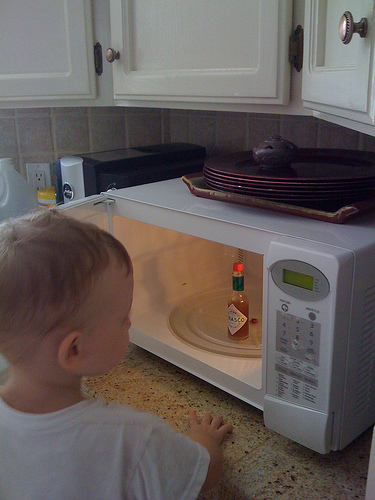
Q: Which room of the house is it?
A: It is a kitchen.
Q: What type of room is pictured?
A: It is a kitchen.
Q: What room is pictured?
A: It is a kitchen.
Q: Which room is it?
A: It is a kitchen.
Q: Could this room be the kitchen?
A: Yes, it is the kitchen.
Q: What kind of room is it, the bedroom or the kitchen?
A: It is the kitchen.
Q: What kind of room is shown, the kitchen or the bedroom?
A: It is the kitchen.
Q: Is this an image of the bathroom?
A: No, the picture is showing the kitchen.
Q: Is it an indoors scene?
A: Yes, it is indoors.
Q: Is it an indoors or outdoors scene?
A: It is indoors.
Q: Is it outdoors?
A: No, it is indoors.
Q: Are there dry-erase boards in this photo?
A: No, there are no dry-erase boards.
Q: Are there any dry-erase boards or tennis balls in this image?
A: No, there are no dry-erase boards or tennis balls.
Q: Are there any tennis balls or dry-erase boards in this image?
A: No, there are no dry-erase boards or tennis balls.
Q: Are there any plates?
A: Yes, there is a plate.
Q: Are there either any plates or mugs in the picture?
A: Yes, there is a plate.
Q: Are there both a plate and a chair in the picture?
A: No, there is a plate but no chairs.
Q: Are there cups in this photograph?
A: No, there are no cups.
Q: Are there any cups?
A: No, there are no cups.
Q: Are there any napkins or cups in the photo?
A: No, there are no cups or napkins.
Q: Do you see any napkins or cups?
A: No, there are no cups or napkins.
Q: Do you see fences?
A: No, there are no fences.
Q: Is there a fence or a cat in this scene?
A: No, there are no fences or cats.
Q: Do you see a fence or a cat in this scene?
A: No, there are no fences or cats.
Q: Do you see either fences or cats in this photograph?
A: No, there are no fences or cats.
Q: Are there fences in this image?
A: No, there are no fences.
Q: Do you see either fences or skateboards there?
A: No, there are no fences or skateboards.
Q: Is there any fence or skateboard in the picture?
A: No, there are no fences or skateboards.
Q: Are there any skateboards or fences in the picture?
A: No, there are no fences or skateboards.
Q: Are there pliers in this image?
A: No, there are no pliers.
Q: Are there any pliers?
A: No, there are no pliers.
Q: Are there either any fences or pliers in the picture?
A: No, there are no pliers or fences.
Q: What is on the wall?
A: The electric outlet is on the wall.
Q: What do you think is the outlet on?
A: The outlet is on the wall.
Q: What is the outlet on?
A: The outlet is on the wall.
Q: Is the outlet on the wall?
A: Yes, the outlet is on the wall.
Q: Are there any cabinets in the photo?
A: Yes, there is a cabinet.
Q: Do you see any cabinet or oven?
A: Yes, there is a cabinet.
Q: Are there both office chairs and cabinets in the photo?
A: No, there is a cabinet but no office chairs.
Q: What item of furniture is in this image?
A: The piece of furniture is a cabinet.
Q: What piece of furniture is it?
A: The piece of furniture is a cabinet.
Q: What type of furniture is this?
A: This is a cabinet.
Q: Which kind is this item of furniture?
A: This is a cabinet.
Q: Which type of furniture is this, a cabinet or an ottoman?
A: This is a cabinet.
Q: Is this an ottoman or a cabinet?
A: This is a cabinet.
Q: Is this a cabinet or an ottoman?
A: This is a cabinet.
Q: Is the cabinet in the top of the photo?
A: Yes, the cabinet is in the top of the image.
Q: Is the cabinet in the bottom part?
A: No, the cabinet is in the top of the image.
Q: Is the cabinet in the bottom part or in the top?
A: The cabinet is in the top of the image.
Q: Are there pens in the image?
A: No, there are no pens.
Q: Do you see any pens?
A: No, there are no pens.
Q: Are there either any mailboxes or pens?
A: No, there are no pens or mailboxes.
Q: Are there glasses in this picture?
A: No, there are no glasses.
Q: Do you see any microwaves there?
A: Yes, there is a microwave.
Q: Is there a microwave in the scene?
A: Yes, there is a microwave.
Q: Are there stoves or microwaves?
A: Yes, there is a microwave.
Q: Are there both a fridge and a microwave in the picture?
A: No, there is a microwave but no refrigerators.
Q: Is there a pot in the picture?
A: No, there are no pots.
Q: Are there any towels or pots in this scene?
A: No, there are no pots or towels.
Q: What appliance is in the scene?
A: The appliance is a microwave.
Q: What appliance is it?
A: The appliance is a microwave.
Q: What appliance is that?
A: This is a microwave.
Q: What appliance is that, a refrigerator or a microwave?
A: This is a microwave.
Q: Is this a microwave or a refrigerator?
A: This is a microwave.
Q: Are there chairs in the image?
A: No, there are no chairs.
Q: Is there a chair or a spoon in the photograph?
A: No, there are no chairs or spoons.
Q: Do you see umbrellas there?
A: No, there are no umbrellas.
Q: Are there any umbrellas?
A: No, there are no umbrellas.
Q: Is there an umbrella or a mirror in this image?
A: No, there are no umbrellas or mirrors.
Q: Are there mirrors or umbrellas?
A: No, there are no umbrellas or mirrors.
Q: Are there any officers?
A: No, there are no officers.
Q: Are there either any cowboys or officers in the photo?
A: No, there are no officers or cowboys.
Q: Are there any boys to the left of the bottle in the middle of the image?
A: Yes, there is a boy to the left of the bottle.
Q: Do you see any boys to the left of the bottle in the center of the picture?
A: Yes, there is a boy to the left of the bottle.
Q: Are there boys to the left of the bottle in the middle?
A: Yes, there is a boy to the left of the bottle.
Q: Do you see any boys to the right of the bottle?
A: No, the boy is to the left of the bottle.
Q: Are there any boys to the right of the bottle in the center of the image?
A: No, the boy is to the left of the bottle.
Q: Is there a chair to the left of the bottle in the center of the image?
A: No, there is a boy to the left of the bottle.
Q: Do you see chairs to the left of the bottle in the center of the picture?
A: No, there is a boy to the left of the bottle.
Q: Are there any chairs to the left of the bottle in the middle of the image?
A: No, there is a boy to the left of the bottle.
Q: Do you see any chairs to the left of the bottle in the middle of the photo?
A: No, there is a boy to the left of the bottle.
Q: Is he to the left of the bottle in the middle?
A: Yes, the boy is to the left of the bottle.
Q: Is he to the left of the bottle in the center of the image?
A: Yes, the boy is to the left of the bottle.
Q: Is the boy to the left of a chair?
A: No, the boy is to the left of the bottle.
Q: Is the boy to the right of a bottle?
A: No, the boy is to the left of a bottle.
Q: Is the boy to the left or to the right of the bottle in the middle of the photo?
A: The boy is to the left of the bottle.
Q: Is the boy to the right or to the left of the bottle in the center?
A: The boy is to the left of the bottle.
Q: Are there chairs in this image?
A: No, there are no chairs.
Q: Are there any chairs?
A: No, there are no chairs.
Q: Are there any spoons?
A: No, there are no spoons.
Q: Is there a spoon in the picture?
A: No, there are no spoons.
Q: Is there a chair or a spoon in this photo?
A: No, there are no spoons or chairs.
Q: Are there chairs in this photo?
A: No, there are no chairs.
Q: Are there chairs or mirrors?
A: No, there are no chairs or mirrors.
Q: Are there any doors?
A: Yes, there is a door.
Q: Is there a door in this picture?
A: Yes, there is a door.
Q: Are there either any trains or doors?
A: Yes, there is a door.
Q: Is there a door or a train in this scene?
A: Yes, there is a door.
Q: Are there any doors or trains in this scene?
A: Yes, there is a door.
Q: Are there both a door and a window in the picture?
A: No, there is a door but no windows.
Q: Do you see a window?
A: No, there are no windows.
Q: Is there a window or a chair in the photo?
A: No, there are no windows or chairs.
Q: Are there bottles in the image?
A: Yes, there is a bottle.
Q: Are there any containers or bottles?
A: Yes, there is a bottle.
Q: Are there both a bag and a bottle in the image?
A: No, there is a bottle but no bags.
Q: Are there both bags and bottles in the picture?
A: No, there is a bottle but no bags.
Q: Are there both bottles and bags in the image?
A: No, there is a bottle but no bags.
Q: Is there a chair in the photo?
A: No, there are no chairs.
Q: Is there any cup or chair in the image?
A: No, there are no chairs or cups.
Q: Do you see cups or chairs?
A: No, there are no chairs or cups.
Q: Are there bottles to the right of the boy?
A: Yes, there is a bottle to the right of the boy.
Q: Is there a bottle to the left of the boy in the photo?
A: No, the bottle is to the right of the boy.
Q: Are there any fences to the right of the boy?
A: No, there is a bottle to the right of the boy.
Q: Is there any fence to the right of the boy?
A: No, there is a bottle to the right of the boy.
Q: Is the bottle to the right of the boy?
A: Yes, the bottle is to the right of the boy.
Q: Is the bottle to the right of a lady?
A: No, the bottle is to the right of the boy.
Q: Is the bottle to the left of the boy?
A: No, the bottle is to the right of the boy.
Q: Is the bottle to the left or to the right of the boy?
A: The bottle is to the right of the boy.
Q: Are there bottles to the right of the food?
A: Yes, there is a bottle to the right of the food.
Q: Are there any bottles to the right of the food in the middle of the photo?
A: Yes, there is a bottle to the right of the food.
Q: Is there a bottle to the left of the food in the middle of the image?
A: No, the bottle is to the right of the food.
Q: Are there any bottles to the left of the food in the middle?
A: No, the bottle is to the right of the food.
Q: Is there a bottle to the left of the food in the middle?
A: No, the bottle is to the right of the food.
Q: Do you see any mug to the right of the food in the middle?
A: No, there is a bottle to the right of the food.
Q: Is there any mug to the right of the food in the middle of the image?
A: No, there is a bottle to the right of the food.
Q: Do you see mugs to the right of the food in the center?
A: No, there is a bottle to the right of the food.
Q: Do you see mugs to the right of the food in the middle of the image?
A: No, there is a bottle to the right of the food.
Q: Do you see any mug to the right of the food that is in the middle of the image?
A: No, there is a bottle to the right of the food.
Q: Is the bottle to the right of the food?
A: Yes, the bottle is to the right of the food.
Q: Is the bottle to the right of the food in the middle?
A: Yes, the bottle is to the right of the food.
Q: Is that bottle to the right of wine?
A: No, the bottle is to the right of the food.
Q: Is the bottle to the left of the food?
A: No, the bottle is to the right of the food.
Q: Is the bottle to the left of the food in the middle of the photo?
A: No, the bottle is to the right of the food.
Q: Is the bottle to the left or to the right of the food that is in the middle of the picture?
A: The bottle is to the right of the food.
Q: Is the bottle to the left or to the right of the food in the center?
A: The bottle is to the right of the food.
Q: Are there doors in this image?
A: Yes, there is a door.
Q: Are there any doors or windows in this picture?
A: Yes, there is a door.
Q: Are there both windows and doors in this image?
A: No, there is a door but no windows.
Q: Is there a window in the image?
A: No, there are no windows.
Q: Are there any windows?
A: No, there are no windows.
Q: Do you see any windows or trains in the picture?
A: No, there are no windows or trains.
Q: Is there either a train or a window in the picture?
A: No, there are no windows or trains.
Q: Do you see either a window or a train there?
A: No, there are no windows or trains.